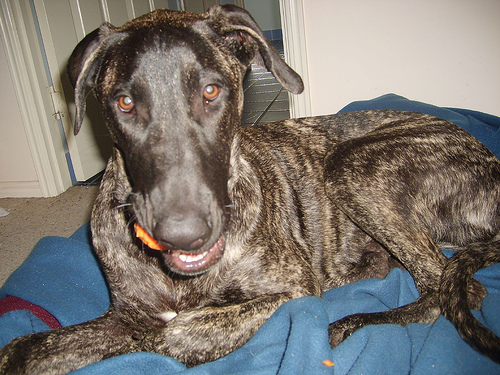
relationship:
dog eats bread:
[15, 14, 499, 361] [132, 222, 169, 255]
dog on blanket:
[0, 0, 500, 375] [15, 256, 495, 373]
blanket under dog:
[244, 288, 405, 367] [52, 13, 495, 330]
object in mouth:
[131, 225, 166, 252] [132, 191, 232, 277]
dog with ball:
[15, 14, 499, 361] [132, 221, 168, 253]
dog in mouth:
[15, 14, 499, 361] [153, 231, 228, 276]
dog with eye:
[15, 14, 499, 361] [200, 84, 217, 101]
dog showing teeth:
[15, 14, 499, 361] [174, 246, 213, 263]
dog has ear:
[15, 14, 499, 361] [205, 0, 335, 125]